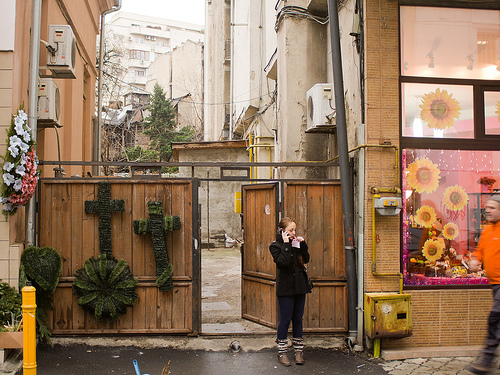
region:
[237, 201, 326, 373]
a woman talking on her cell phone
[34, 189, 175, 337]
wreaths hanging on the wall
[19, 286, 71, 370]
a yellow pole in street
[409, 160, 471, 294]
sunflowers in a window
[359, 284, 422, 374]
a yellow gas meter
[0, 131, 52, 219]
flowers hanging on the wall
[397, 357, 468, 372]
white bricks in the sidewalk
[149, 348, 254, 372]
black pavement near a building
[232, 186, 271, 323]
wooden gate behind a lady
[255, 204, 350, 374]
a woman wearing brown boots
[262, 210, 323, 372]
Woman standing on the street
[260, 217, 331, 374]
Woman wears black cloths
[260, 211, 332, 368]
Girl is talking by phone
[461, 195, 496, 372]
Man walking in the street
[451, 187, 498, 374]
Man wears orange sweatshirt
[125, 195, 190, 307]
Brown cross over fence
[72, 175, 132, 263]
Brown cross over fence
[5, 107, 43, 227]
Flowers hanging on the wall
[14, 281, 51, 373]
Yellow pole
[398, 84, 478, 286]
Sunflowers on the window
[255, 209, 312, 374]
this is a lady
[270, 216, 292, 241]
the lady is speaking through the phone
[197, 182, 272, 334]
the gate is opened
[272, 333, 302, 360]
the lady is wearing brown boots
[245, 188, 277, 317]
the gate is wooden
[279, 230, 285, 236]
the hand is holding cell phone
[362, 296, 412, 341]
the metallic bin is rusty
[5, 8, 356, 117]
these are houses behind the lady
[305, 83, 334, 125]
this is a white fan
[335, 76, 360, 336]
the pipe is black in color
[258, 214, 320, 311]
woman holding phone to ear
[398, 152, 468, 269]
sunflowers in store window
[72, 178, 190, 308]
crosses on wood fence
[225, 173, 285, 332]
open wood gate door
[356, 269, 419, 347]
yellow utility box on building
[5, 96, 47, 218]
flowers on corner of building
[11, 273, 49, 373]
yellow pole in sidewalk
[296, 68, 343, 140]
air conditioner in building wall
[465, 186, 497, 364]
man in orange walking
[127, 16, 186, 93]
balconies on tall building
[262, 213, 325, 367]
A girl talks on the phone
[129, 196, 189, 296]
Artwork designed in the shape of a cross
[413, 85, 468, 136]
A sunflower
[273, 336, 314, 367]
A pair of brown boots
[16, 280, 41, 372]
A yellow pole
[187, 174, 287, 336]
The entrance to a wooden gate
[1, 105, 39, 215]
A bouquet of flowers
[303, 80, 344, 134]
Air conditioning Unit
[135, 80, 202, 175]
A large tree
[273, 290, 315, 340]
A pair of blue jeans